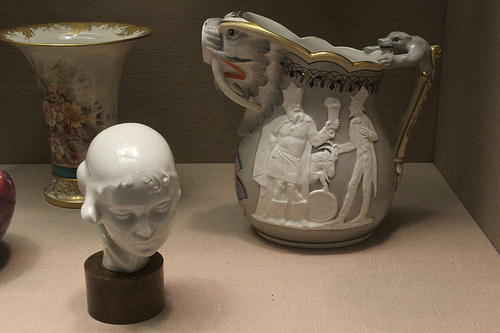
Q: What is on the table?
A: A statue and vases.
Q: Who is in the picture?
A: Nobody.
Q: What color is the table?
A: White.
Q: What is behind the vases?
A: The wall.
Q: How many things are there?
A: Three.